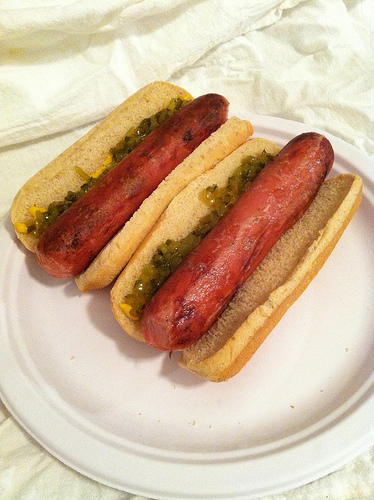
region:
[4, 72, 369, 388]
two hot dogs on a bun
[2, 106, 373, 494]
white plate holding two hot dogs on a bun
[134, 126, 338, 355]
actual cooked hot dog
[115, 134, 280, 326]
green chopped up relish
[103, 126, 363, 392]
white breaded hot dog bun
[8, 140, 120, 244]
a bit of yellow mustard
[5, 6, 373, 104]
white cloth near hot dog plate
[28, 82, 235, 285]
a cooked hot dog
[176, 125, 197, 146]
small burn areas on cooked hot dog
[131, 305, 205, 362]
end of hot dog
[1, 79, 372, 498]
Two hot dogs on a white paper plate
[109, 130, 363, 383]
Hot dog on a bun with relish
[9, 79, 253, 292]
Hot dog on a bun with mustard and relish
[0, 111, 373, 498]
white paper plate on table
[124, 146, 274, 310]
Relish on a hot dog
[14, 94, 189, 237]
Relish and mustard on hot dog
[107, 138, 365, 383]
Hot dog roll holding hot dog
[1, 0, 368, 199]
White material under plate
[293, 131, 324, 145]
Charred edge of hot dog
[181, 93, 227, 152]
Charred marks on hot dog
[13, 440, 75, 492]
the table mat is whit in color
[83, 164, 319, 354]
the sandwich are apetising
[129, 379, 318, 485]
the plate is white in color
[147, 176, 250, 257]
a green paste of margarine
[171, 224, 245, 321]
sausage is red in color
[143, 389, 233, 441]
pieces of bread on the plate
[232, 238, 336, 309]
the bread is brown in color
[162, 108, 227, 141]
sausage has black spots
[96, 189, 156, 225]
part if the red colored sausage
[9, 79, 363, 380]
two hot dogs on buns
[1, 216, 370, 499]
round white paper plate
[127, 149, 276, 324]
green relish on hot dog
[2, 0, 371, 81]
white tablecloth on table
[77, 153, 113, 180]
yellow mustard under relish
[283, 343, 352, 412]
crumbs from hot dog bun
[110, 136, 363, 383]
wheat hot dog bun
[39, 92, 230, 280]
grilled hot dog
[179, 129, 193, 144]
char mark on hot dog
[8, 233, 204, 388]
shadow of hot dogs on plate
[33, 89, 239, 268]
a cooked brown wrinkly hot dog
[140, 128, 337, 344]
a cooked brown wrinkly hot dog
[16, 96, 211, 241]
green relish on a hot dog bun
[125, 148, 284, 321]
green relish on a hot dog bun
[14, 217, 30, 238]
a dob of yellow mustard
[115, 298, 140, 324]
a dob of yellow mustard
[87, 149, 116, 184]
a dob of yellow mustard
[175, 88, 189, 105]
a dob of yellow mustard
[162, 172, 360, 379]
a part of a hot dog bun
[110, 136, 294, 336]
a part of a hot dog bun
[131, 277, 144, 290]
green relish on the hot dog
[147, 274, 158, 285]
green relish on the hot dog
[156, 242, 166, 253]
green relish on the hot dog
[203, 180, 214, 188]
green relish on the hot dog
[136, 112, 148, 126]
green relish on the hot dog